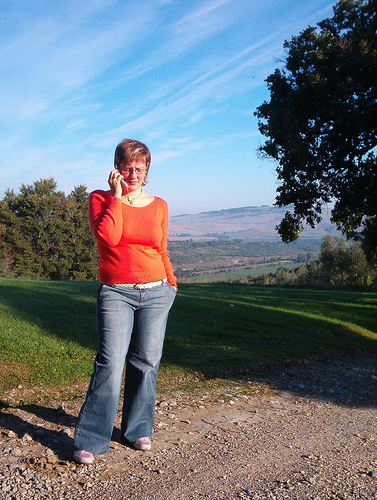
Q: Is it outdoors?
A: Yes, it is outdoors.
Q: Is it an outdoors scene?
A: Yes, it is outdoors.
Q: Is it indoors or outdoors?
A: It is outdoors.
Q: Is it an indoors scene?
A: No, it is outdoors.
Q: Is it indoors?
A: No, it is outdoors.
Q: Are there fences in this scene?
A: No, there are no fences.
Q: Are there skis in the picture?
A: No, there are no skis.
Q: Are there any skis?
A: No, there are no skis.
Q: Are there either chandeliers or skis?
A: No, there are no skis or chandeliers.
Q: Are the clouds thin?
A: Yes, the clouds are thin.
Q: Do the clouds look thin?
A: Yes, the clouds are thin.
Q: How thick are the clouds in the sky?
A: The clouds are thin.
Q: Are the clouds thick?
A: No, the clouds are thin.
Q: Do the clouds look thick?
A: No, the clouds are thin.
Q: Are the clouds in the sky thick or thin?
A: The clouds are thin.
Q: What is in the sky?
A: The clouds are in the sky.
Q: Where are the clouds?
A: The clouds are in the sky.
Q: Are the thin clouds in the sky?
A: Yes, the clouds are in the sky.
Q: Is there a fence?
A: No, there are no fences.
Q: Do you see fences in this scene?
A: No, there are no fences.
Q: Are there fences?
A: No, there are no fences.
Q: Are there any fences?
A: No, there are no fences.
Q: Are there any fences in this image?
A: No, there are no fences.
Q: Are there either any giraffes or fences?
A: No, there are no fences or giraffes.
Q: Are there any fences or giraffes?
A: No, there are no fences or giraffes.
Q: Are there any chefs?
A: No, there are no chefs.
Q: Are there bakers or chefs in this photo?
A: No, there are no chefs or bakers.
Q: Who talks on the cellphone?
A: The lady talks on the cellphone.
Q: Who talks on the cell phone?
A: The lady talks on the cellphone.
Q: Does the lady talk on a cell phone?
A: Yes, the lady talks on a cell phone.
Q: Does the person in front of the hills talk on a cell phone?
A: Yes, the lady talks on a cell phone.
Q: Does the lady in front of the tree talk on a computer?
A: No, the lady talks on a cell phone.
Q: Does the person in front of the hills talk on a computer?
A: No, the lady talks on a cell phone.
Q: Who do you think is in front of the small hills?
A: The lady is in front of the hills.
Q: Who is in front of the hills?
A: The lady is in front of the hills.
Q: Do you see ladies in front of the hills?
A: Yes, there is a lady in front of the hills.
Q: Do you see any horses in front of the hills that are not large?
A: No, there is a lady in front of the hills.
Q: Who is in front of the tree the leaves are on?
A: The lady is in front of the tree.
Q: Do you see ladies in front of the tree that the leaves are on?
A: Yes, there is a lady in front of the tree.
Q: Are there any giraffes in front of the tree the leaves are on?
A: No, there is a lady in front of the tree.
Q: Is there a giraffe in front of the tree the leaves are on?
A: No, there is a lady in front of the tree.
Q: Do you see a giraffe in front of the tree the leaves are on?
A: No, there is a lady in front of the tree.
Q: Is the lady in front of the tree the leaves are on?
A: Yes, the lady is in front of the tree.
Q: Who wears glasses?
A: The lady wears glasses.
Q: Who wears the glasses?
A: The lady wears glasses.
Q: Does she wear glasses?
A: Yes, the lady wears glasses.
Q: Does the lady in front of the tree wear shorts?
A: No, the lady wears glasses.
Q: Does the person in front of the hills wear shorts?
A: No, the lady wears glasses.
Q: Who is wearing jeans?
A: The lady is wearing jeans.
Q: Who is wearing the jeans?
A: The lady is wearing jeans.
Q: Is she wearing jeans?
A: Yes, the lady is wearing jeans.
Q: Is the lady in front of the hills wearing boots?
A: No, the lady is wearing jeans.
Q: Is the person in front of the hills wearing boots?
A: No, the lady is wearing jeans.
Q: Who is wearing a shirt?
A: The lady is wearing a shirt.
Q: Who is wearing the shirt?
A: The lady is wearing a shirt.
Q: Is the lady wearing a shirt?
A: Yes, the lady is wearing a shirt.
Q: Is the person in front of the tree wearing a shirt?
A: Yes, the lady is wearing a shirt.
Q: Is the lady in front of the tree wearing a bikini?
A: No, the lady is wearing a shirt.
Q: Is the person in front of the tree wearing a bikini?
A: No, the lady is wearing a shirt.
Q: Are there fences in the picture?
A: No, there are no fences.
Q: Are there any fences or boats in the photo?
A: No, there are no fences or boats.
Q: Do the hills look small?
A: Yes, the hills are small.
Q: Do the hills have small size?
A: Yes, the hills are small.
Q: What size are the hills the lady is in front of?
A: The hills are small.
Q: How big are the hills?
A: The hills are small.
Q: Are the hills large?
A: No, the hills are small.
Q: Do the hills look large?
A: No, the hills are small.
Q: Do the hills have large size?
A: No, the hills are small.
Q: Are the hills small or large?
A: The hills are small.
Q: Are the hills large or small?
A: The hills are small.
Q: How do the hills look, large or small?
A: The hills are small.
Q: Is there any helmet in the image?
A: No, there are no helmets.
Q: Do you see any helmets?
A: No, there are no helmets.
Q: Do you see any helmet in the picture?
A: No, there are no helmets.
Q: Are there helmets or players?
A: No, there are no helmets or players.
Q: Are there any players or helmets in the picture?
A: No, there are no helmets or players.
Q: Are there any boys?
A: No, there are no boys.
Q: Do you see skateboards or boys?
A: No, there are no boys or skateboards.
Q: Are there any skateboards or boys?
A: No, there are no boys or skateboards.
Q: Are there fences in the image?
A: No, there are no fences.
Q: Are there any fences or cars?
A: No, there are no fences or cars.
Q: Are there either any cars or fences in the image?
A: No, there are no fences or cars.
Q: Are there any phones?
A: Yes, there is a phone.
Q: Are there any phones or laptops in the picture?
A: Yes, there is a phone.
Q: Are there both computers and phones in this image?
A: No, there is a phone but no computers.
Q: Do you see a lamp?
A: No, there are no lamps.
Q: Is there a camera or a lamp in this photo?
A: No, there are no lamps or cameras.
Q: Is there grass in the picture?
A: Yes, there is grass.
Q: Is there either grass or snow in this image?
A: Yes, there is grass.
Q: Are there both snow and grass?
A: No, there is grass but no snow.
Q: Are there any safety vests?
A: No, there are no safety vests.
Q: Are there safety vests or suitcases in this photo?
A: No, there are no safety vests or suitcases.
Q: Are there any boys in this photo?
A: No, there are no boys.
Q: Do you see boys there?
A: No, there are no boys.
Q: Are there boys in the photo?
A: No, there are no boys.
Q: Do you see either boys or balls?
A: No, there are no boys or balls.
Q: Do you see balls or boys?
A: No, there are no boys or balls.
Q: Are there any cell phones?
A: Yes, there is a cell phone.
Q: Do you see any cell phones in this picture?
A: Yes, there is a cell phone.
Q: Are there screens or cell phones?
A: Yes, there is a cell phone.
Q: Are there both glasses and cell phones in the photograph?
A: Yes, there are both a cell phone and glasses.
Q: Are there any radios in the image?
A: No, there are no radios.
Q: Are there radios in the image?
A: No, there are no radios.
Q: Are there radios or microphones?
A: No, there are no radios or microphones.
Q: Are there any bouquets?
A: No, there are no bouquets.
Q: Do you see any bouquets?
A: No, there are no bouquets.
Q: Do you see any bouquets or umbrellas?
A: No, there are no bouquets or umbrellas.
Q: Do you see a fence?
A: No, there are no fences.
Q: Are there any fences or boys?
A: No, there are no fences or boys.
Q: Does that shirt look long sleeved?
A: Yes, the shirt is long sleeved.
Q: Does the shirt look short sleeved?
A: No, the shirt is long sleeved.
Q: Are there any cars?
A: No, there are no cars.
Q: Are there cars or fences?
A: No, there are no cars or fences.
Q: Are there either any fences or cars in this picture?
A: No, there are no cars or fences.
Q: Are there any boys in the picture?
A: No, there are no boys.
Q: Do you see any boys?
A: No, there are no boys.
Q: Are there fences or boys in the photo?
A: No, there are no boys or fences.